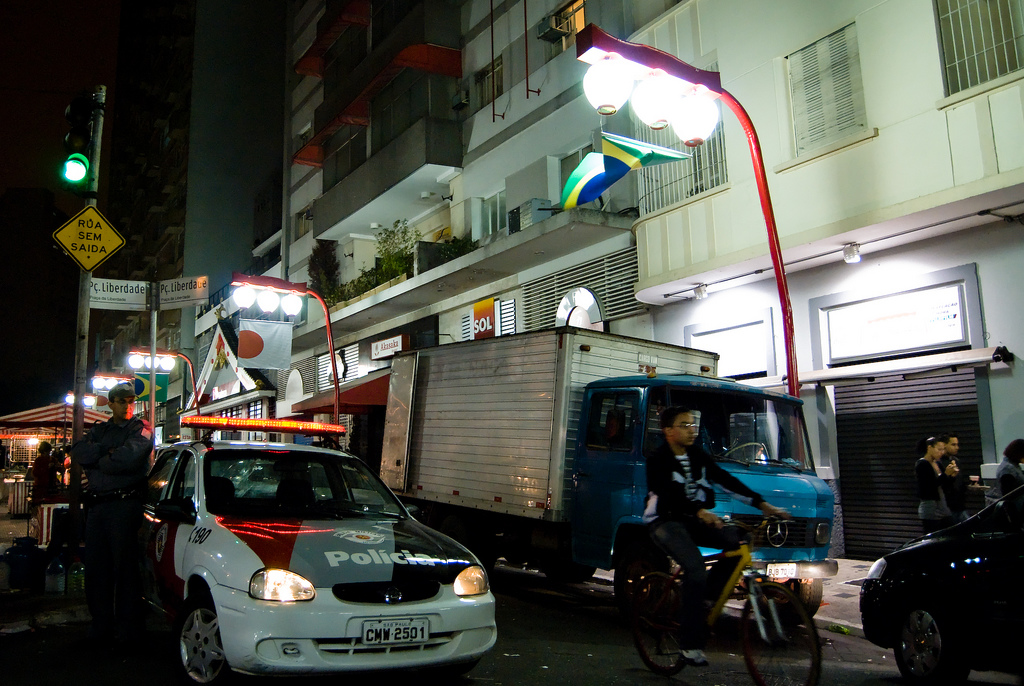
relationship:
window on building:
[750, 40, 886, 197] [214, 0, 1021, 545]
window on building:
[942, 10, 1015, 83] [611, 3, 1018, 563]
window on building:
[607, 75, 776, 253] [214, 0, 1021, 545]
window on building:
[838, 331, 927, 534] [214, 0, 1021, 545]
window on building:
[811, 281, 984, 366] [214, 0, 1021, 545]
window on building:
[485, 49, 531, 120] [214, 0, 1021, 545]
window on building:
[462, 187, 513, 232] [214, 0, 1021, 545]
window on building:
[433, 324, 466, 338] [214, 0, 1021, 545]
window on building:
[449, 274, 516, 314] [214, 0, 1020, 545]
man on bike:
[598, 390, 818, 682] [614, 515, 827, 686]